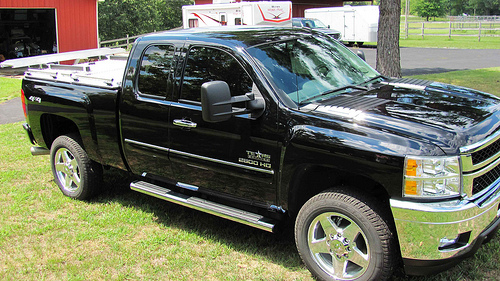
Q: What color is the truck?
A: Black.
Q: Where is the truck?
A: In grass.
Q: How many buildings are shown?
A: One.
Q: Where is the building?
A: Behind truck.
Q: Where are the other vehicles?
A: On pavement.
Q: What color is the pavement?
A: Gray.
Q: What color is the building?
A: Red.